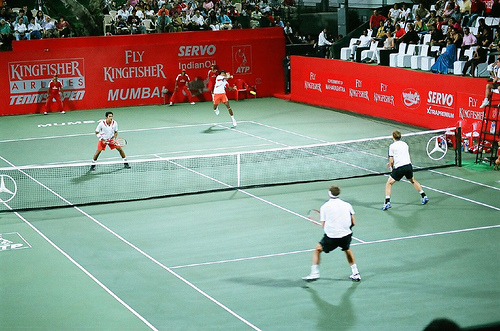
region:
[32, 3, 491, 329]
a doubles tennis match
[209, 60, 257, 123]
man returning ball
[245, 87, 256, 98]
tennis ball flying through air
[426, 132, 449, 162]
Mercedes logo on net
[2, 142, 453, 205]
black and white tennis net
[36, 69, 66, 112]
line judge wearing red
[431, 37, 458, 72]
woman in long blue robes sitting in stands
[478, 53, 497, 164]
tennis umpire chair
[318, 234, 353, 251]
black shorts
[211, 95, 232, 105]
red tennis shorts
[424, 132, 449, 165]
Mercedes Benz logo on net.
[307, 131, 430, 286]
Men playing partners in tennis match.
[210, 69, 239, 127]
Man serving at tennis match.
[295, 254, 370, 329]
Shadow of man on court.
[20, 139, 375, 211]
Black and white tennis net.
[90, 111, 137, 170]
Man wearing red and white outfit.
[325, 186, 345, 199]
Man wearing white headband.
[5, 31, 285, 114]
Red and white advertisement wall.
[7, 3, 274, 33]
Spectators watching tennis match.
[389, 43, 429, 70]
White chairs in stand.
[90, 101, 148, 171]
Tennis player on the court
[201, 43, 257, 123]
tennis player hitting the ball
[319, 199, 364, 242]
man wearing a white shirt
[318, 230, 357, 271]
man wearing black shorts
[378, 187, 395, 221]
man wearing blue sneakers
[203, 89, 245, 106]
man wearing orange shorts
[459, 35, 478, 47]
man wearing pink shirt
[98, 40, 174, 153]
advertisements on the wall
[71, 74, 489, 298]
people playing tennis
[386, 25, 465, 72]
people watching a tennis match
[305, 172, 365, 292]
This is a person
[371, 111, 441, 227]
This is a person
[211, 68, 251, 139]
This is a person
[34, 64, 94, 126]
This is a person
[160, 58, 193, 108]
This is a person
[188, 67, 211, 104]
This is a person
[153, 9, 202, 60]
This is a person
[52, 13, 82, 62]
This is a person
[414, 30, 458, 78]
This is a person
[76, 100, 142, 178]
Man in white shirt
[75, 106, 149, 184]
Man in red shorts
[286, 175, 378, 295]
Man in black shorts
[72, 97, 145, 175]
Man in black shoes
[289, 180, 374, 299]
Man in white shoes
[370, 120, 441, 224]
Man in blue shoes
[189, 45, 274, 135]
Man hitting a tennis ball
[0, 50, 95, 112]
Kingfisher Airlines logo on wall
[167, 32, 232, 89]
Servo Logo on wall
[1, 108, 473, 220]
Tennis net in center of field